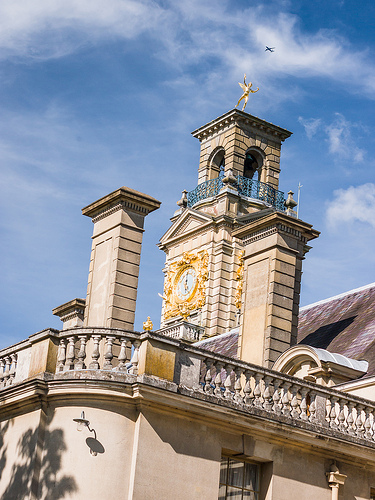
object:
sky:
[1, 0, 373, 353]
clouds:
[0, 0, 373, 240]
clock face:
[175, 267, 197, 299]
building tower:
[149, 68, 317, 404]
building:
[0, 67, 375, 500]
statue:
[234, 72, 260, 110]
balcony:
[0, 323, 375, 464]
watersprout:
[326, 471, 347, 489]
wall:
[0, 395, 375, 500]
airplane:
[264, 43, 278, 54]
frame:
[161, 252, 213, 323]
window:
[221, 449, 271, 498]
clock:
[160, 249, 212, 327]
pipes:
[324, 461, 344, 500]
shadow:
[84, 423, 104, 455]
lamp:
[74, 408, 90, 431]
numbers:
[176, 268, 195, 299]